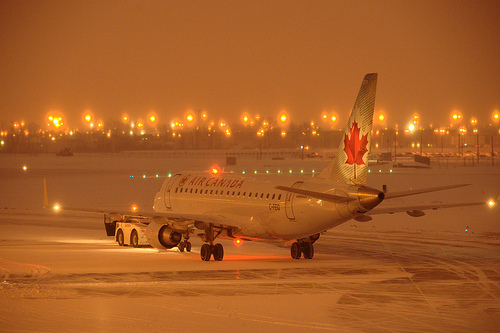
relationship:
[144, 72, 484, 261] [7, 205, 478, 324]
aeroplane on tarmac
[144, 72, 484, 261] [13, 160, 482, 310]
aeroplane on runway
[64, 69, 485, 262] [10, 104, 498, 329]
aeroplane in an airport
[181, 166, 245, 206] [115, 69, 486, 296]
red writing on plane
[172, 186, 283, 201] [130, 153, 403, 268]
window on plane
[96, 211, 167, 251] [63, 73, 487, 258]
car in front of plane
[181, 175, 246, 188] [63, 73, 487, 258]
name on plane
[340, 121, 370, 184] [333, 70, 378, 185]
red leaf on tail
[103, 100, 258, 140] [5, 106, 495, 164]
lights in vista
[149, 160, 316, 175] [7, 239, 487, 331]
lights on runway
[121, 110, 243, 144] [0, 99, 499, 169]
houses in distance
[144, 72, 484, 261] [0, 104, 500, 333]
aeroplane on airport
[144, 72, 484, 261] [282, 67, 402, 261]
aeroplane has back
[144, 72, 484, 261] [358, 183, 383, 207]
aeroplane has tip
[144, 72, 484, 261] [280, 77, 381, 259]
aeroplane has back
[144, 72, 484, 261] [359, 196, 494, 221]
aeroplane has left wing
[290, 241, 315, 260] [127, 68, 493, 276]
wheel on plane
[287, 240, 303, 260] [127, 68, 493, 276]
wheel on plane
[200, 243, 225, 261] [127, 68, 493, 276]
wheel on plane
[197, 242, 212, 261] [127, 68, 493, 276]
wheel on plane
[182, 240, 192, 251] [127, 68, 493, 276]
wheel on plane